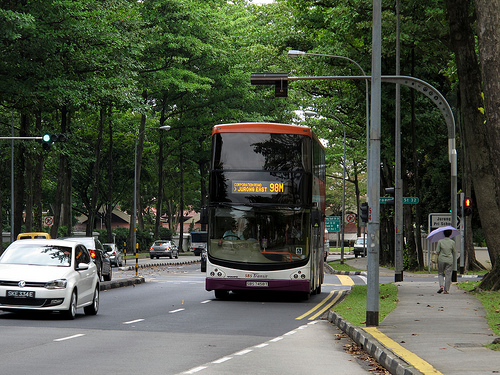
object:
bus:
[198, 122, 326, 302]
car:
[0, 237, 102, 320]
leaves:
[190, 42, 194, 45]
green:
[70, 30, 94, 59]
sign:
[232, 180, 289, 194]